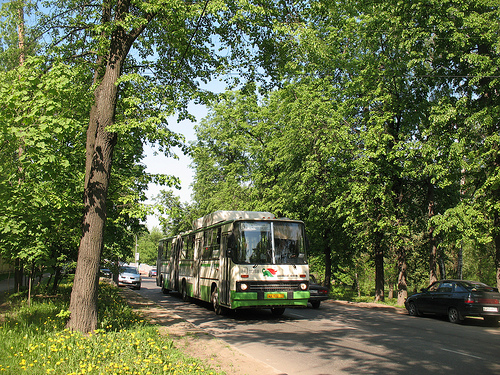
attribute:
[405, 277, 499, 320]
car — parked, white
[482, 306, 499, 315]
license plate — white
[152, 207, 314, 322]
bus — white, large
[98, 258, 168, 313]
car — parked, white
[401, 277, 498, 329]
car — black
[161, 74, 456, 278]
trees — leafy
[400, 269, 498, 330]
car — black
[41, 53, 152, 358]
trunk — large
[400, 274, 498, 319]
car — black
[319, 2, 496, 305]
trees — leafy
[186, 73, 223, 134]
sky — blue, bright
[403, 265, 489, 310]
car — black